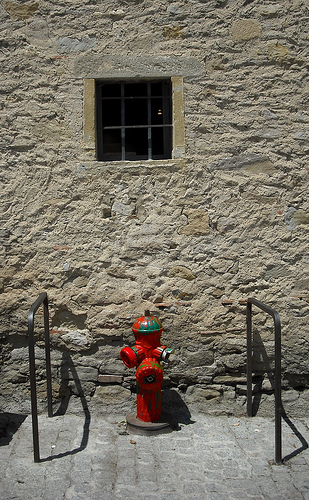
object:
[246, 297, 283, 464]
rail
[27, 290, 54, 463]
rail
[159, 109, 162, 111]
light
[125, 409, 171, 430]
base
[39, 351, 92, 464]
shadow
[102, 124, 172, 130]
bars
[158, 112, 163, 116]
light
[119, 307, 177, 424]
hydrant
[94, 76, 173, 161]
window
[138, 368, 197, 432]
shadow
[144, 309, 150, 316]
bolt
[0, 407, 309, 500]
sidewalk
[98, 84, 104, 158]
bars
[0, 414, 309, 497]
ground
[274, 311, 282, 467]
pole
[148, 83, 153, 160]
bar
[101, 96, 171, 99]
bars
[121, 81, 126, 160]
bars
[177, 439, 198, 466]
bricks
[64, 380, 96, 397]
brick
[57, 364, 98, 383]
brick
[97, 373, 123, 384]
brick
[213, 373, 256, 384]
brick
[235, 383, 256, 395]
brick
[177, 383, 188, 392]
brick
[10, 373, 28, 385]
brick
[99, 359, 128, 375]
brick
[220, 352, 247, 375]
brick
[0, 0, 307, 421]
building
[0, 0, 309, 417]
wall